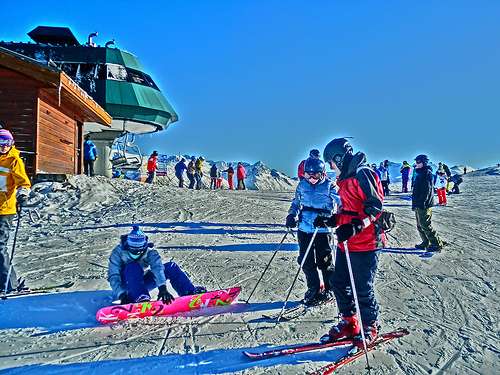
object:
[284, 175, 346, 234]
jacket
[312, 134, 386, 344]
person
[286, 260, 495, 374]
snow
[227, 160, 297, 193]
hill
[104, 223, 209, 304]
person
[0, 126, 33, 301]
person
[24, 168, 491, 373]
snow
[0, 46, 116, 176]
building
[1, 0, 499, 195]
sky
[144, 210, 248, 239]
shadow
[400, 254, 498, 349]
snow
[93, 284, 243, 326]
skateboarder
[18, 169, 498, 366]
ground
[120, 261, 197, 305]
pants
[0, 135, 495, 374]
snow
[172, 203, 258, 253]
snow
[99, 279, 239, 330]
snowboard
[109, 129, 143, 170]
metal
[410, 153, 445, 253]
person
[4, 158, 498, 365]
snow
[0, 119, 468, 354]
people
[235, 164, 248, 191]
person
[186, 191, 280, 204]
snow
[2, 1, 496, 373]
picture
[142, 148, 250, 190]
group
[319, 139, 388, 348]
skiers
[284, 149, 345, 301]
skiers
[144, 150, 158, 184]
person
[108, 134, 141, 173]
ski lift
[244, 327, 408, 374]
skis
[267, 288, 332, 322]
skis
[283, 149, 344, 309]
person